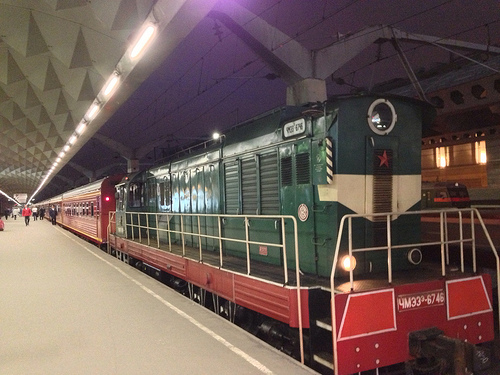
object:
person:
[21, 204, 31, 226]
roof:
[2, 0, 499, 203]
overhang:
[49, 12, 168, 161]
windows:
[59, 200, 101, 217]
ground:
[0, 212, 500, 375]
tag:
[396, 289, 447, 313]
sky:
[117, 105, 203, 118]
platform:
[0, 216, 320, 372]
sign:
[281, 115, 307, 141]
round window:
[365, 97, 397, 137]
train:
[27, 89, 499, 375]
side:
[114, 99, 337, 279]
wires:
[91, 0, 500, 177]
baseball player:
[422, 135, 488, 188]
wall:
[419, 87, 500, 206]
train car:
[24, 90, 499, 375]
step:
[310, 287, 334, 370]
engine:
[106, 86, 500, 375]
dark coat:
[47, 208, 59, 218]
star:
[373, 148, 394, 173]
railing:
[106, 210, 500, 375]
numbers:
[412, 292, 447, 309]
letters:
[398, 292, 446, 309]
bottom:
[108, 234, 500, 374]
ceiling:
[0, 0, 158, 172]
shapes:
[0, 0, 159, 205]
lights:
[23, 20, 158, 204]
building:
[0, 0, 499, 371]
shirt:
[22, 208, 30, 217]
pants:
[24, 216, 29, 225]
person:
[50, 203, 57, 225]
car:
[29, 92, 499, 375]